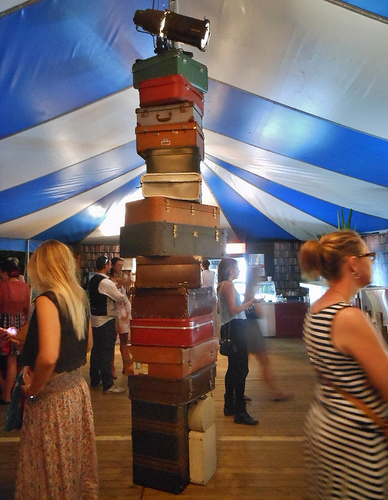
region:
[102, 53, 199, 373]
stack of suitcases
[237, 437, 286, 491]
wooden plank floor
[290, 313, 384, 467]
woman wearing a striped dress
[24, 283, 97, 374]
woman wearing a black midriff shirt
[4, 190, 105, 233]
blue and white tent over head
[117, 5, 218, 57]
large light on top of the suitcases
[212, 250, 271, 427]
person standing behind the suitcases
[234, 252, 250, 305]
light shining in from outside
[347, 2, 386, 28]
metal tent pole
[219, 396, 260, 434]
person is wearing black boots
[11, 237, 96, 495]
A woman with her hands on her hips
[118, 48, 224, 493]
A large stack of luggage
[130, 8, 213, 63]
A light on the luggage stack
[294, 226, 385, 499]
A woman in a black and white dress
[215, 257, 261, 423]
A woman wearing a blue blouse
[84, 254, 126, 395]
A man wearing a black vest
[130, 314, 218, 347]
A red piece of luggage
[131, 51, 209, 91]
A green piece of luggage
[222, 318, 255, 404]
Black pants on the woman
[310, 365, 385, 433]
A brown purse strap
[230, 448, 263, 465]
this is the floor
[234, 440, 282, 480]
the floor is wooden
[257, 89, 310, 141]
this is a tent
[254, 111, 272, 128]
the tent is blue in color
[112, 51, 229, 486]
these are several suitcases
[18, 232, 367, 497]
these are some people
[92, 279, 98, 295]
the coat is black in color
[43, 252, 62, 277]
the hair is blonde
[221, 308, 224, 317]
the blouse is pink in color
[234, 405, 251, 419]
the shoe is black in color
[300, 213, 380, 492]
this is a lady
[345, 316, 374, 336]
the lady is light skinned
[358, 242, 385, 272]
this is a spectacle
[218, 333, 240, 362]
this is a bag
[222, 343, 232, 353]
the bag is black in color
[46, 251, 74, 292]
this is the hair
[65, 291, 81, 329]
the hair is long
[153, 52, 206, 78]
this is a box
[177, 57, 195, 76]
the box is metallic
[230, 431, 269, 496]
this is the floor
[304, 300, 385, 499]
the woman is wearing a dress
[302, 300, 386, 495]
the dress is made of stripes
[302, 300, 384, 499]
the stripes are black and white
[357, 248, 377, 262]
the woman is wearing glasses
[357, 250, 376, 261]
the glasses are black in color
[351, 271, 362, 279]
the woman is wearing an ear ring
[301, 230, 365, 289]
the woman's hair is tied back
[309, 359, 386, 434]
a strap is across the body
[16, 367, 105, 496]
the woman is wearinga skirt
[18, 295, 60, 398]
the woman has her hand on her hip